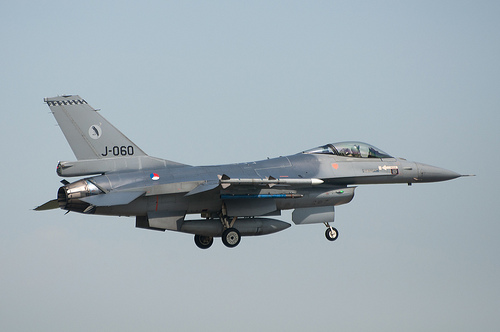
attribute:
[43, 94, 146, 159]
tail wing — gray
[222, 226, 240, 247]
wheel — white, black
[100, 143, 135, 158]
id — black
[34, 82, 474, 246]
jet — grey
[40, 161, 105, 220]
tail — silver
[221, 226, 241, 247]
wheel — black, white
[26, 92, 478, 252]
plane — gray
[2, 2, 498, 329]
sky — bluish gray, hazy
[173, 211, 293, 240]
warhead — large, gray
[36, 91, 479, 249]
fighter jet — gray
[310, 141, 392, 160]
windshield — glass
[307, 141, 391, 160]
window — small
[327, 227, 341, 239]
wheel — black, white